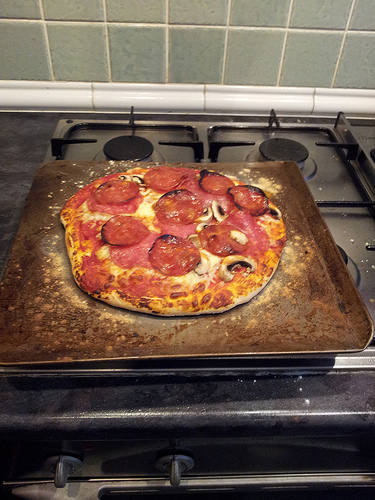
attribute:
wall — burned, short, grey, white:
[2, 3, 373, 113]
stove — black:
[41, 112, 375, 361]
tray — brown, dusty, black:
[13, 158, 368, 374]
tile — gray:
[1, 1, 374, 89]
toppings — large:
[93, 168, 270, 275]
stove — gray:
[0, 111, 374, 498]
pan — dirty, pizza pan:
[0, 160, 374, 367]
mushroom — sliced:
[217, 254, 255, 280]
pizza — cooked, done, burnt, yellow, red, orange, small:
[61, 165, 286, 316]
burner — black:
[207, 108, 374, 206]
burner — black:
[48, 105, 203, 162]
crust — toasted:
[59, 167, 286, 315]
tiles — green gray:
[0, 1, 374, 119]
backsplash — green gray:
[0, 0, 375, 122]